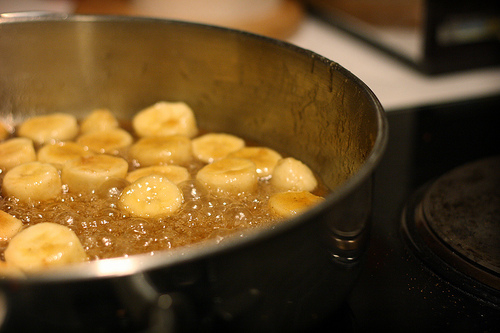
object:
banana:
[1, 162, 59, 202]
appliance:
[300, 0, 499, 73]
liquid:
[0, 136, 328, 262]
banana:
[133, 102, 196, 137]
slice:
[192, 133, 245, 163]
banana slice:
[119, 175, 183, 217]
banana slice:
[195, 158, 257, 194]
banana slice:
[272, 158, 316, 191]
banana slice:
[269, 190, 327, 217]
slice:
[4, 163, 61, 200]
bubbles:
[127, 219, 151, 236]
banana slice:
[199, 159, 255, 190]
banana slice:
[226, 147, 283, 176]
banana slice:
[62, 154, 127, 192]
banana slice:
[5, 222, 86, 271]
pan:
[0, 15, 387, 333]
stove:
[422, 164, 499, 270]